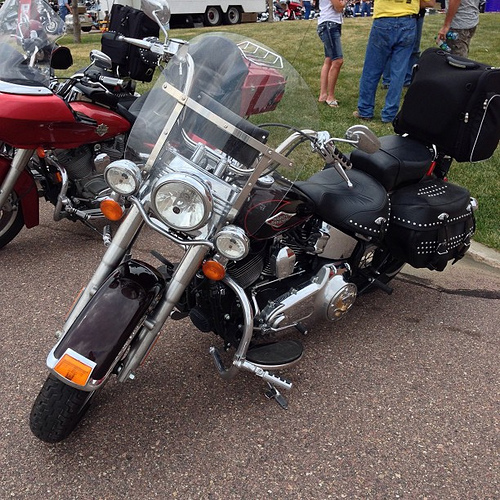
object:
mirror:
[345, 124, 382, 154]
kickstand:
[242, 335, 304, 370]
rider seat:
[349, 132, 432, 192]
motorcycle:
[27, 0, 480, 446]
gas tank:
[238, 173, 318, 243]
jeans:
[357, 13, 417, 123]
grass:
[50, 14, 500, 246]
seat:
[290, 161, 392, 242]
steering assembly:
[29, 31, 351, 442]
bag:
[386, 177, 477, 270]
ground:
[0, 12, 492, 494]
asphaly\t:
[2, 185, 498, 498]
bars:
[114, 31, 199, 169]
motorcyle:
[0, 2, 289, 250]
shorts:
[317, 21, 345, 62]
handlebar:
[268, 128, 353, 190]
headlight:
[149, 172, 214, 234]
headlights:
[101, 157, 144, 198]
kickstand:
[258, 369, 290, 411]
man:
[351, 0, 437, 124]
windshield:
[121, 29, 320, 237]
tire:
[27, 259, 167, 445]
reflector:
[54, 353, 92, 386]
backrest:
[396, 77, 462, 140]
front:
[27, 8, 371, 447]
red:
[7, 96, 49, 126]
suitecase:
[392, 41, 498, 165]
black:
[421, 69, 456, 130]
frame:
[0, 92, 132, 225]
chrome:
[47, 155, 69, 199]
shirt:
[371, 0, 424, 20]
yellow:
[378, 0, 390, 13]